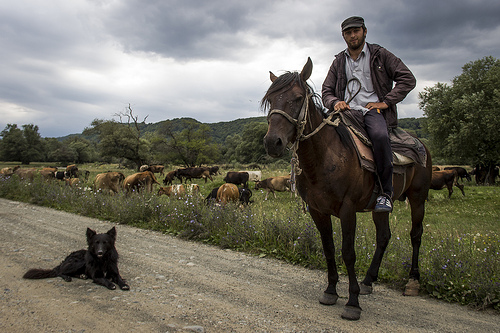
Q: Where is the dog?
A: In the road.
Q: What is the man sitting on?
A: Horse.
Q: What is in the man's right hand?
A: Reins.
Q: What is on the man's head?
A: Hat.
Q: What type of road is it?
A: Dirt.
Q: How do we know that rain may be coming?
A: Clouds.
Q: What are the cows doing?
A: Grazing.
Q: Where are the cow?
A: In a pasture.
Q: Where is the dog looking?
A: Into the camera.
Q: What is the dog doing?
A: Lying down.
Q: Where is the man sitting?
A: Horseback.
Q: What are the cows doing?
A: Grazing grass.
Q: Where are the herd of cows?
A: Grassy field.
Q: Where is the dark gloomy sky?
A: Above the trees.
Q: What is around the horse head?
A: A bridles.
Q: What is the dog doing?
A: Laying on the street.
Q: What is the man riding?
A: A horse.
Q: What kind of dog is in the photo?
A: A black collie.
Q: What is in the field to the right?
A: Cattle.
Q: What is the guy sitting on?
A: A horse.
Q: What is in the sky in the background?
A: Clouds.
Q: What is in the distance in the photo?
A: Mountains.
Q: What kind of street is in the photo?
A: Dirt road.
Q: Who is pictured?
A: A man.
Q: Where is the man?
A: On the horse.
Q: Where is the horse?
A: On the road.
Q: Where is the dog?
A: On the road.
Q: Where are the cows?
A: In the field.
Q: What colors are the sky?
A: Blue, white.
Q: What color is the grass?
A: Green.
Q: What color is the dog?
A: Black.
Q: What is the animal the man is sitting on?
A: Horse.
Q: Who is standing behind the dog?
A: No one.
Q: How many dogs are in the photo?
A: One.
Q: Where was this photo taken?
A: Rural field.